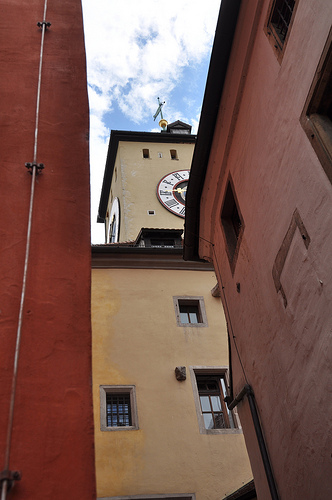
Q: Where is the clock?
A: On the tower.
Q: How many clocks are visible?
A: One.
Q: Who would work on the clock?
A: Clocksmith.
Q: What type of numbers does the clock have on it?
A: Roman numerals.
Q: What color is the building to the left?
A: Red.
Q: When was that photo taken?
A: Daytime.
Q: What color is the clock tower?
A: Yellow.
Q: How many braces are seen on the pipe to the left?
A: Three.